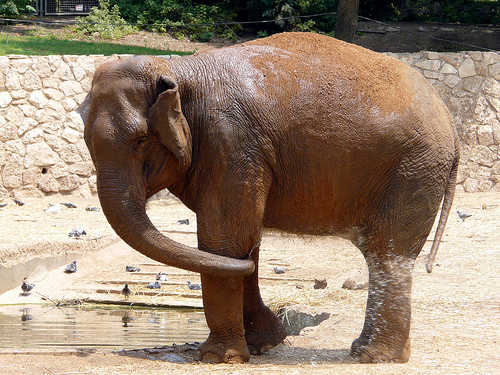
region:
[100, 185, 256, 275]
Long brown trunk of an elephant.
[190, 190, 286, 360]
Tow front brown legs of an elephant.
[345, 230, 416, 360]
Two back legs of a brown elephant.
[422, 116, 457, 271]
Long skinny elephant tail.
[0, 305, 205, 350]
Water in front of an elephant.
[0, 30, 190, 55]
Green grass above the rock wall.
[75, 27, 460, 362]
A large brown elephant.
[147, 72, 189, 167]
A brown elephants left ear.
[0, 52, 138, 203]
Large tan rock wall in front of an elephant.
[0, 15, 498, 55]
A thin rope going all along the top of the rock wall.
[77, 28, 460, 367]
giant elephant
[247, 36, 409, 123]
dirt on the elephants back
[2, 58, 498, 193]
rock wall behind the elephant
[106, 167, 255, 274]
the elephant's trunk around his front leg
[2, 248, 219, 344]
a pool of water on the ground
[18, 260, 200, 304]
several pigeons by the elephant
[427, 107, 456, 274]
the elephant's tail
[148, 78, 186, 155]
the elephant's left ear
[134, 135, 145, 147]
the elephant's left eye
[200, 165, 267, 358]
the elephant's front left leg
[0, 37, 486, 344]
elephant in the photo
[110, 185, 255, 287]
trunk of the elephant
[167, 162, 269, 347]
leg of the elephant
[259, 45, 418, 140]
dirt on the elephant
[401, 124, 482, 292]
tail of the elephant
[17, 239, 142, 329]
birds near the elephant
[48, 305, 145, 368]
water next to elephant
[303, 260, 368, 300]
rocks on the ground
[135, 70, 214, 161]
ear of the elephant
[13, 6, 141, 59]
grass in the background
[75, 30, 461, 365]
the elephant standing in the enclosure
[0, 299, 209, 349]
the water near the elephant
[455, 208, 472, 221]
the bird on the ground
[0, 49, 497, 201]
the wall for the enclosure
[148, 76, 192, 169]
the ear on the elephant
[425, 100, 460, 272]
the tail on the elephant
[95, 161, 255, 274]
the trunk on the elephant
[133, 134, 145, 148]
the eye on the elephant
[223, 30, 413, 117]
the dirt on the elephant's back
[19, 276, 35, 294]
the bird near the water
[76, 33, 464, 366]
a huge animal outside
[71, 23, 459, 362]
the animal is an elephant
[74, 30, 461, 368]
the elephant is gray and brown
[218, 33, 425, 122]
dirt is on the elephat's back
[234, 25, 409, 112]
the dirt is a medium brown color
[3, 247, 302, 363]
water is around the elephant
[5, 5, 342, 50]
bushes are around the area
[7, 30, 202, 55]
the grass is very pretty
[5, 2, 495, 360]
it is bright outside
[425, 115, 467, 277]
the tail of the elephant